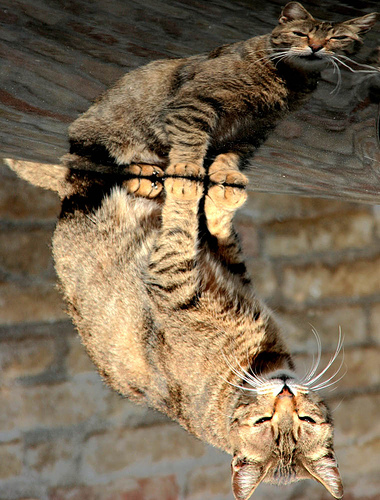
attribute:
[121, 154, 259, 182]
paw — sharp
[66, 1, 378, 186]
cat — black-striped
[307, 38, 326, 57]
nose — brown, black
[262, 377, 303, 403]
nose — pink, triangular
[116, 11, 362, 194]
cat — tabby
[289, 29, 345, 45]
eyes — semi closed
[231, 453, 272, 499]
ear — pointy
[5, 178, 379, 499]
wall — brick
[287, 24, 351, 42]
eyes — black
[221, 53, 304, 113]
chest — brown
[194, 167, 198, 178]
claw — white